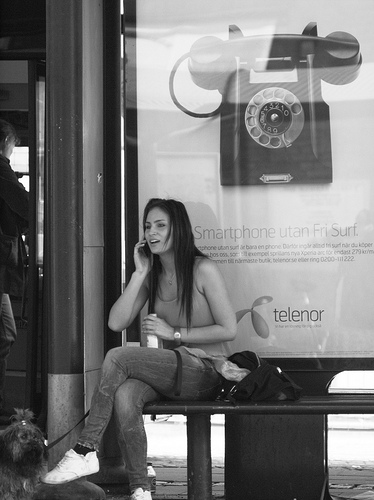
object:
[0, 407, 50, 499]
dog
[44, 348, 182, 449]
leash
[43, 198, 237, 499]
woman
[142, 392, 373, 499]
bench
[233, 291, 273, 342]
logo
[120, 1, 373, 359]
advertisement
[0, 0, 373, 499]
bus stop shelter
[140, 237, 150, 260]
cell phone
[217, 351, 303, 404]
purse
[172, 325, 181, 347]
wristwatch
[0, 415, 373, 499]
ground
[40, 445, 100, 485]
sneaker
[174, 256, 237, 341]
left arm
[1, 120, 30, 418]
passenger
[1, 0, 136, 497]
bus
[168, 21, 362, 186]
telephone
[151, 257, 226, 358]
tanktop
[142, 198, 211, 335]
hair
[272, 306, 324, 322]
telenor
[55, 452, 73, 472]
lace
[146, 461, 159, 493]
bottle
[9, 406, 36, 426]
ponytail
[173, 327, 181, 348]
white face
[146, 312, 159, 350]
object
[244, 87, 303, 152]
dial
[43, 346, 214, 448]
woman's leg